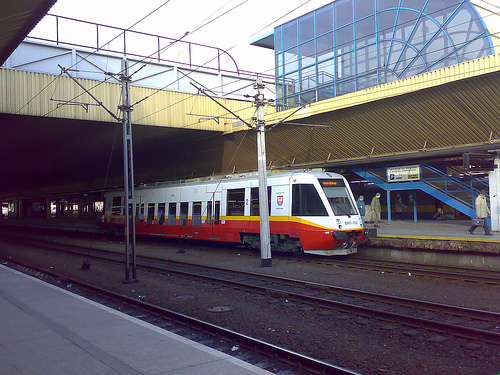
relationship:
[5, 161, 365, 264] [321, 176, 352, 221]
train has a windshield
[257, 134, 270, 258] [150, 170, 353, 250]
pole on right side of train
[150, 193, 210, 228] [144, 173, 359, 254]
windows are on right side of train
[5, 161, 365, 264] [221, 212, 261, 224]
train has a gold strip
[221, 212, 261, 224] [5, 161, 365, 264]
strip on side of train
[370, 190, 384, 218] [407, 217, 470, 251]
man walking on platform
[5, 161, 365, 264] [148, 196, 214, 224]
train has windows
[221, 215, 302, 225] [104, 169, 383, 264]
strip on train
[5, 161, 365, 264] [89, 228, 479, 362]
train on tracks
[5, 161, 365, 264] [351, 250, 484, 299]
train on tracks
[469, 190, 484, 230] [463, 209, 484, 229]
man with briefcase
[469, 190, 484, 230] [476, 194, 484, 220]
man with coat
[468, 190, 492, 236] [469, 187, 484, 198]
man with hat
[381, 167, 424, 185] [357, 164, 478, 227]
sign with staircase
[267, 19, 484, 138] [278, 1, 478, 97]
wall with windows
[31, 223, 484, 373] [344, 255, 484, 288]
lanes with tracks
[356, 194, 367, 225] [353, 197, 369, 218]
men with jacket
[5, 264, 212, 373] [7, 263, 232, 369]
platform with stripe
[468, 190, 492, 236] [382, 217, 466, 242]
man on platform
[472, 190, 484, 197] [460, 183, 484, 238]
hat on man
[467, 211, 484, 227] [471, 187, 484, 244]
briefcase with man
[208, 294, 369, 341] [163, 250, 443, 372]
gravel between tracks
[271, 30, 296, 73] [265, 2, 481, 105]
window on building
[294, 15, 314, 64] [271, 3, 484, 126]
window on building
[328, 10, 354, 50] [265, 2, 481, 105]
window on building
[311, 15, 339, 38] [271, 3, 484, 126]
window on building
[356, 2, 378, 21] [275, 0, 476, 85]
window on building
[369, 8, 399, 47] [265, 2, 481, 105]
window on building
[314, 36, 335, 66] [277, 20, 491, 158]
window on building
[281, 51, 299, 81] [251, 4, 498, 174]
window on building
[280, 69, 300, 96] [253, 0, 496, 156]
window on building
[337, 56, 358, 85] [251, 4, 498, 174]
window on building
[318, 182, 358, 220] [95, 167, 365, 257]
window on train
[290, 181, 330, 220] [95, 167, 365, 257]
window on train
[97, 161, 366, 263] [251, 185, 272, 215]
train on window